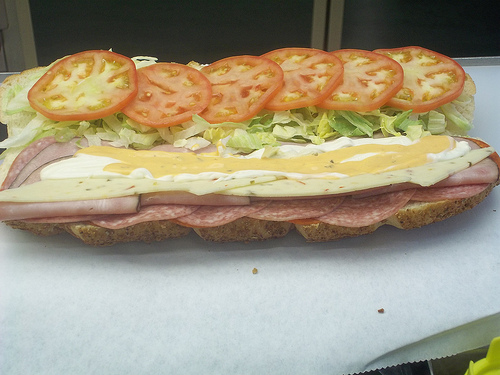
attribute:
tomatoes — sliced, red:
[25, 24, 462, 127]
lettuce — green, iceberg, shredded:
[56, 115, 446, 128]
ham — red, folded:
[9, 193, 478, 196]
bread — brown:
[6, 135, 495, 254]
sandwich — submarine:
[6, 32, 498, 291]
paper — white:
[9, 59, 498, 374]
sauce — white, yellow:
[17, 137, 470, 166]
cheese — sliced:
[15, 171, 482, 199]